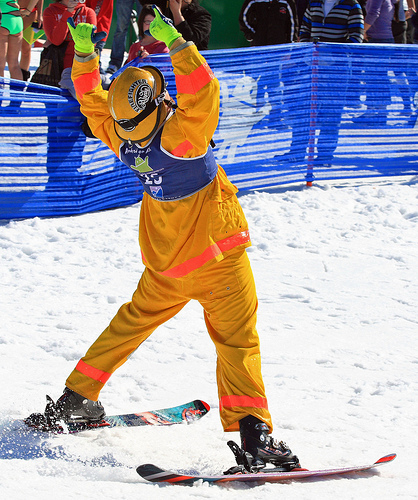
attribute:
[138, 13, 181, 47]
gloves — green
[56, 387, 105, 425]
boot — black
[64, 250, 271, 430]
pants — orange, reflective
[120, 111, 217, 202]
vest — blue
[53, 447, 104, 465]
snow — spraying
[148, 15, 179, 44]
gloves — green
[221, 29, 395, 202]
fence — blue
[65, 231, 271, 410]
pants — yellow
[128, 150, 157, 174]
robot — Android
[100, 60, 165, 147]
helmet — yellow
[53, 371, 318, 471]
boot — snowboot